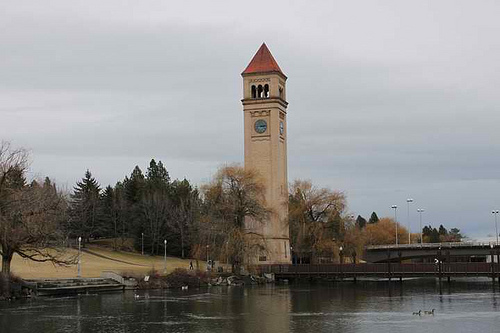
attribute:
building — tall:
[238, 37, 298, 280]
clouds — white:
[7, 70, 96, 146]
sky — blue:
[3, 29, 238, 149]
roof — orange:
[240, 39, 290, 79]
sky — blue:
[4, 0, 466, 181]